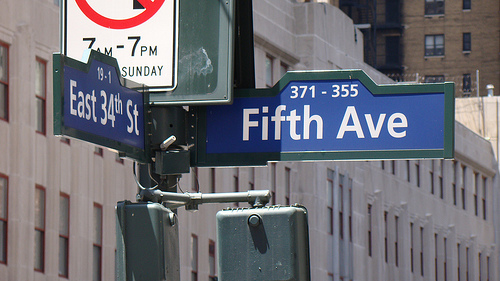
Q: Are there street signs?
A: Yes, there is a street sign.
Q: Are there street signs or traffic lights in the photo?
A: Yes, there is a street sign.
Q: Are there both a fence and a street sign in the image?
A: No, there is a street sign but no fences.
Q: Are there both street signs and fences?
A: No, there is a street sign but no fences.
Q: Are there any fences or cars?
A: No, there are no cars or fences.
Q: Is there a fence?
A: No, there are no fences.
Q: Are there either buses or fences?
A: No, there are no fences or buses.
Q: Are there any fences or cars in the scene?
A: No, there are no fences or cars.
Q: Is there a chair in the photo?
A: No, there are no chairs.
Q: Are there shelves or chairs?
A: No, there are no chairs or shelves.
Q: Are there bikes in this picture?
A: No, there are no bikes.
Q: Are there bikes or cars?
A: No, there are no bikes or cars.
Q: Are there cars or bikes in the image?
A: No, there are no bikes or cars.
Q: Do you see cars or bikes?
A: No, there are no bikes or cars.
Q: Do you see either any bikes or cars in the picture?
A: No, there are no bikes or cars.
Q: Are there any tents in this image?
A: No, there are no tents.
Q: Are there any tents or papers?
A: No, there are no tents or papers.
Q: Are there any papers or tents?
A: No, there are no tents or papers.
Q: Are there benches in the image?
A: No, there are no benches.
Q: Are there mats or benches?
A: No, there are no benches or mats.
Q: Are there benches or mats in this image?
A: No, there are no benches or mats.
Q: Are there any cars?
A: No, there are no cars.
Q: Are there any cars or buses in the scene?
A: No, there are no cars or buses.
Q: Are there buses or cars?
A: No, there are no cars or buses.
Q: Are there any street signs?
A: Yes, there is a street sign.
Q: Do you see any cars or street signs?
A: Yes, there is a street sign.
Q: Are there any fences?
A: No, there are no fences.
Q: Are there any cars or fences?
A: No, there are no fences or cars.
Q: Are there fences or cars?
A: No, there are no fences or cars.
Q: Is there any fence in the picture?
A: No, there are no fences.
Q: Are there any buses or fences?
A: No, there are no fences or buses.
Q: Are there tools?
A: No, there are no tools.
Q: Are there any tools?
A: No, there are no tools.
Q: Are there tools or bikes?
A: No, there are no tools or bikes.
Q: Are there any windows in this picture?
A: Yes, there are windows.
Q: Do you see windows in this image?
A: Yes, there are windows.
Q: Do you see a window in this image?
A: Yes, there are windows.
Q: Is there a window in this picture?
A: Yes, there are windows.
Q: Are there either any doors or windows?
A: Yes, there are windows.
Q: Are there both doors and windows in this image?
A: No, there are windows but no doors.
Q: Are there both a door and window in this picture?
A: No, there are windows but no doors.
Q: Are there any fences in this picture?
A: No, there are no fences.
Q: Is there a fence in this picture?
A: No, there are no fences.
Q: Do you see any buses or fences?
A: No, there are no fences or buses.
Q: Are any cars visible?
A: No, there are no cars.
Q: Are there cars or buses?
A: No, there are no cars or buses.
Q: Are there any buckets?
A: No, there are no buckets.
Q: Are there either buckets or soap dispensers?
A: No, there are no buckets or soap dispensers.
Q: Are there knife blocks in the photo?
A: No, there are no knife blocks.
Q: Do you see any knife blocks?
A: No, there are no knife blocks.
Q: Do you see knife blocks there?
A: No, there are no knife blocks.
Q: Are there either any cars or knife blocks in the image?
A: No, there are no knife blocks or cars.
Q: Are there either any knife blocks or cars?
A: No, there are no knife blocks or cars.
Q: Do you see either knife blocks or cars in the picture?
A: No, there are no knife blocks or cars.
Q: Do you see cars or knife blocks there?
A: No, there are no knife blocks or cars.